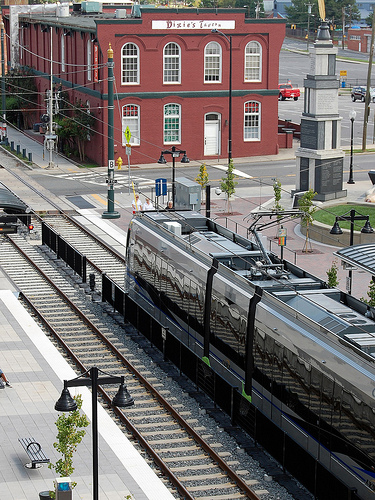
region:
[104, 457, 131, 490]
part of a floor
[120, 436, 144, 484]
part of a floor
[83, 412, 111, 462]
part of a floor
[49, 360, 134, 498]
lanterns at train station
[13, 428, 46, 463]
bench on loading platform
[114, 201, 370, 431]
end of silver train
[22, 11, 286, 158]
large red building on corner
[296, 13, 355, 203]
concrete statue on sidewalk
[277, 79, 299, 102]
red truck in parking lot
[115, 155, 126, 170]
yellow fire hydrant in front of red building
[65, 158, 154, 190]
crosswalk on street in front of red building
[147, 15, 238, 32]
white sign on red building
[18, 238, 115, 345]
train tracks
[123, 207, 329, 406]
a grey and blue train engine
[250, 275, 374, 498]
a grey and blue train engine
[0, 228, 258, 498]
a set of train tracks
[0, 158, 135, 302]
a set of train tracks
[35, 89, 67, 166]
a train crossing signal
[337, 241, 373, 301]
a train roof shelter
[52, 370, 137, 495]
black overhead street light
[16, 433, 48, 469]
a wood park bench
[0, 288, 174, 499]
a train boarding platform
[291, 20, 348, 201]
a tall granite statue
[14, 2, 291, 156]
a Dixie's Tavern Building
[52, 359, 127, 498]
a black light post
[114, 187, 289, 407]
a train on the train tracks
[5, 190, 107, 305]
train tracks on the ground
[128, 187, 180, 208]
people walking on the sidewalk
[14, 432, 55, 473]
a bench on the sidewalk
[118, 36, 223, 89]
windows of the building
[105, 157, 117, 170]
a letter B on the post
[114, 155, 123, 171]
a yellow fire hydrant on the sidewalk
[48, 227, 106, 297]
a barricade between two train tracks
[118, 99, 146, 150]
a window on the building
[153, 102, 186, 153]
a window on the building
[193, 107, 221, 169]
a window on the building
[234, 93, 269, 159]
a window on the building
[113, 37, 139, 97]
a window on the building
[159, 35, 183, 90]
a window on the building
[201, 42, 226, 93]
a window on the building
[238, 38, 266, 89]
a window on the building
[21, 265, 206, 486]
this is a railway line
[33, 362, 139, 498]
this is a light post